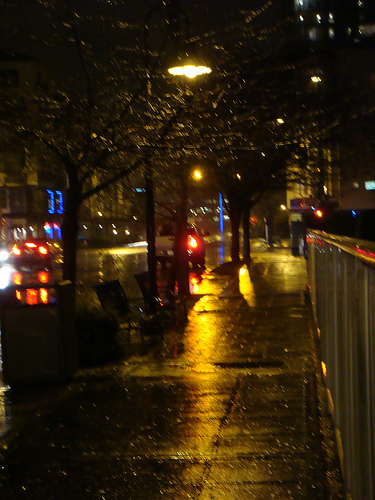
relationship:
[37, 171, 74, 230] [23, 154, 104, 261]
lights in window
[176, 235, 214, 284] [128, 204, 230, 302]
lights of car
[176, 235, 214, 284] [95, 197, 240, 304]
lights on car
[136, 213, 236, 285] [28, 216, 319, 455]
car on road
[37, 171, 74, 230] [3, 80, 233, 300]
lights on building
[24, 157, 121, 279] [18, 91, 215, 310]
lights on building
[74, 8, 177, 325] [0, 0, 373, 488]
tree in city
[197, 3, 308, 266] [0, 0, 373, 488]
tree in city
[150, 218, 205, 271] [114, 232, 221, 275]
truck on road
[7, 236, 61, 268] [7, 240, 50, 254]
car has tail lights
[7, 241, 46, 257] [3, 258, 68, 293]
tail lights on car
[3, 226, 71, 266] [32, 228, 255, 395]
truck on road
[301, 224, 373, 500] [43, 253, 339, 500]
fence along sidewalk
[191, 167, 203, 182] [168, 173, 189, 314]
light on pole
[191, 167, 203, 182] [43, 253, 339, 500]
light on sidewalk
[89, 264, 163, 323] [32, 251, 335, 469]
benches on sidewalk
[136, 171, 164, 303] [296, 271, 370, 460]
poles of fence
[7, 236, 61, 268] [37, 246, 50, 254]
car with lights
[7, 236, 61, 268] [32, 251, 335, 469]
car on sidewalk